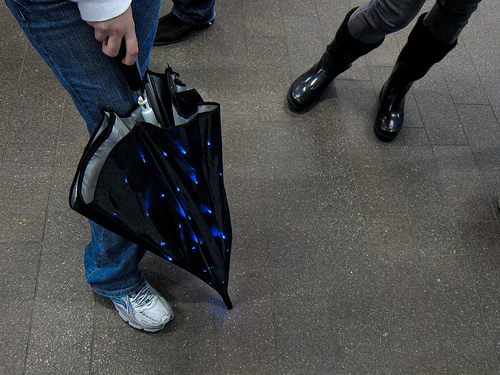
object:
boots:
[284, 4, 468, 142]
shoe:
[109, 272, 174, 335]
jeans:
[4, 0, 165, 298]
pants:
[348, 0, 480, 46]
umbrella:
[66, 37, 234, 311]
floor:
[0, 2, 500, 375]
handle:
[106, 37, 151, 96]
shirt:
[77, 0, 133, 22]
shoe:
[152, 6, 215, 46]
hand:
[85, 9, 140, 67]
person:
[4, 0, 216, 334]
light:
[193, 237, 203, 247]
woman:
[4, 0, 175, 334]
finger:
[122, 35, 140, 65]